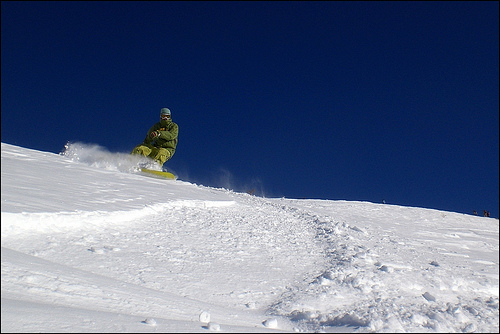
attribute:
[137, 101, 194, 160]
man — active, outdoors, close, here, standing, snowboarding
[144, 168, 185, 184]
board — close, lime green, green, yellow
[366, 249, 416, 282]
snow — flying, deep, here, white